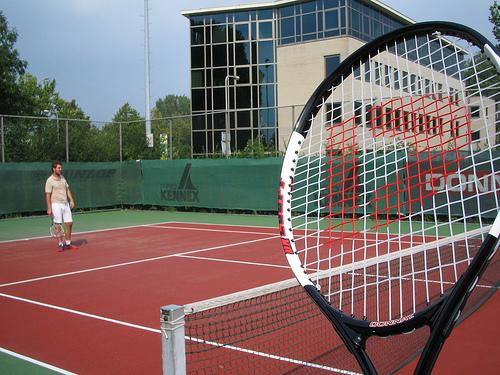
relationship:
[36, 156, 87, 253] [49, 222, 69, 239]
man holding tennis racket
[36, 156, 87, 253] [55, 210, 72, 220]
man wearing shorts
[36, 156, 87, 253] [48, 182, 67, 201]
man wearing shirt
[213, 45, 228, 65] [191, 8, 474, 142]
window in building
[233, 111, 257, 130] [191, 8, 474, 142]
window in building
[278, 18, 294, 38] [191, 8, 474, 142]
window in building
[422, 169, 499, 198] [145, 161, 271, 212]
lettering on fence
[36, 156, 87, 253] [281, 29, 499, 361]
man holding tennis racket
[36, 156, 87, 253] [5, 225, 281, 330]
man standing on court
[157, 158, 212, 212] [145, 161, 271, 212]
logo on fence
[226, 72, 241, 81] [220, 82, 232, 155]
light mounted on pole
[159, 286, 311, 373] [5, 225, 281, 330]
net standing on court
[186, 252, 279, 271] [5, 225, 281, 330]
stripe on court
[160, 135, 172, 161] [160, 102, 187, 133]
sign posted in tree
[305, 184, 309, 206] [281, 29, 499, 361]
string tied in tennis racket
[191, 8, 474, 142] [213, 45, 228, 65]
building has window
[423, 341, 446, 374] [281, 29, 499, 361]
handle of tennis racket